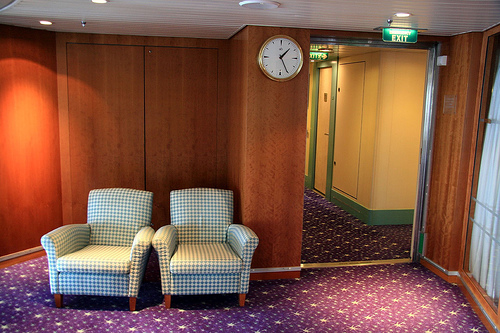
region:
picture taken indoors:
[19, 15, 493, 326]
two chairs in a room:
[23, 110, 295, 302]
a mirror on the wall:
[317, 50, 432, 254]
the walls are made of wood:
[70, 55, 211, 132]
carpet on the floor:
[295, 288, 437, 323]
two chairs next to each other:
[33, 120, 331, 320]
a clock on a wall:
[252, 30, 325, 91]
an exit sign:
[370, 11, 425, 46]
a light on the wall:
[9, 35, 54, 229]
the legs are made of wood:
[160, 288, 255, 306]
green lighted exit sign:
[383, 27, 416, 44]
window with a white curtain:
[470, 54, 497, 305]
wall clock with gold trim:
[258, 35, 302, 78]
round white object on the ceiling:
[239, 1, 278, 9]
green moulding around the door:
[310, 58, 337, 200]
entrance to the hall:
[302, 35, 435, 269]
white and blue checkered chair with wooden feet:
[153, 187, 258, 307]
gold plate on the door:
[323, 92, 326, 102]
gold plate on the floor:
[305, 258, 410, 266]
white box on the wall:
[436, 55, 446, 65]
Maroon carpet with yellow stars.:
[256, 277, 467, 329]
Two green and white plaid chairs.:
[37, 186, 259, 308]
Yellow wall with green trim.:
[312, 49, 407, 233]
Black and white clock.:
[256, 31, 303, 86]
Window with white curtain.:
[456, 22, 497, 329]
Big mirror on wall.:
[298, 39, 429, 271]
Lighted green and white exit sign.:
[381, 26, 418, 46]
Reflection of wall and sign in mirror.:
[310, 37, 428, 250]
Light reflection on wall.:
[1, 44, 81, 222]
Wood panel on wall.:
[6, 49, 240, 185]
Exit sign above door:
[376, 23, 423, 53]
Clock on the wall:
[251, 29, 306, 86]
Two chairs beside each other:
[39, 180, 274, 320]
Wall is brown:
[89, 60, 231, 180]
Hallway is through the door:
[308, 52, 417, 272]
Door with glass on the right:
[451, 68, 498, 331]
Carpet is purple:
[283, 280, 371, 331]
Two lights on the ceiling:
[28, 0, 125, 37]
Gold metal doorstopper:
[297, 258, 414, 270]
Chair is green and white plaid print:
[153, 186, 258, 313]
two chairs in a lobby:
[33, 170, 265, 309]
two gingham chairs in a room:
[30, 179, 260, 309]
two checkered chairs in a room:
[31, 180, 261, 312]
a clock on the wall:
[253, 31, 306, 83]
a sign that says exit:
[376, 25, 424, 50]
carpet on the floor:
[263, 270, 444, 330]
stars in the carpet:
[263, 279, 423, 326]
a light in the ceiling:
[35, 15, 55, 32]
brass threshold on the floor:
[303, 252, 411, 272]